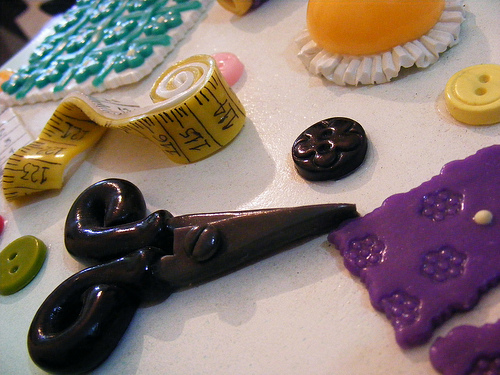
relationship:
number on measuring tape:
[179, 127, 212, 151] [2, 56, 251, 201]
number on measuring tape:
[19, 163, 52, 185] [2, 56, 251, 201]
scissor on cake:
[18, 167, 363, 366] [2, 0, 498, 372]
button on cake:
[433, 69, 496, 124] [2, 0, 498, 372]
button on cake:
[2, 232, 50, 297] [18, 10, 479, 365]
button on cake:
[210, 52, 246, 87] [2, 0, 498, 372]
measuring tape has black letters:
[2, 56, 251, 201] [212, 98, 239, 131]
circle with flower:
[287, 114, 370, 185] [295, 126, 336, 163]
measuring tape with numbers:
[2, 51, 256, 201] [173, 95, 246, 165]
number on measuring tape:
[206, 98, 243, 137] [2, 56, 251, 201]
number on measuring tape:
[166, 119, 218, 161] [2, 56, 251, 201]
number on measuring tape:
[9, 158, 67, 194] [2, 56, 251, 201]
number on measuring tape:
[45, 115, 97, 149] [2, 56, 251, 201]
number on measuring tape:
[166, 124, 211, 155] [2, 56, 251, 201]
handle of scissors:
[25, 177, 168, 374] [26, 177, 360, 373]